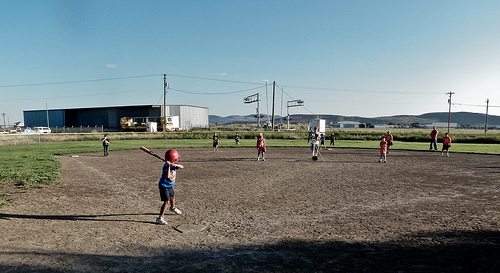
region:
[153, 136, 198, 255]
A kid playing baseball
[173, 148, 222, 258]
A kid playing baseball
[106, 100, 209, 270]
A kid playing baseball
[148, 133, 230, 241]
A kid playing baseball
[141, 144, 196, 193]
A kid playing baseball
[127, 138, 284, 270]
A kid is playing baseball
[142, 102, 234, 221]
A kid is playing baseball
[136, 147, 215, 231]
A kid is playing baseball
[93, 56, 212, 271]
A kid is playing baseball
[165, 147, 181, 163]
Red round baseball helmet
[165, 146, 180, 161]
Baseball helmet is red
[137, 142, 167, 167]
Baseball bat in hand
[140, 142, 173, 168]
Long brown baseball bat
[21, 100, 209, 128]
Long grey rectangular building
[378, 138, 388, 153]
Orange baseball jersey shirt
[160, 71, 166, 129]
Long cylinder powerline pole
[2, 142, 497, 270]
Diamond shaped baseball field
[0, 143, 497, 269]
Dirt covered baseball field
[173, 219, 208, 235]
Pentagon shaped home base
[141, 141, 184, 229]
children playing baseball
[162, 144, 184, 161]
red baseball helmet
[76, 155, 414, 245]
tan dirt baseball field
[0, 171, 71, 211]
patches of green grass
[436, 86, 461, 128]
tall brown telephone pole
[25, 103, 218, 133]
grey warehouse in background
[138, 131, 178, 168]
brown and black baseball bat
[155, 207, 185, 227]
small white tennis shoes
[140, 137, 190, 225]
child holding baseball bat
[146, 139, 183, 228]
child wearing white tennis shoes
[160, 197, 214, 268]
A kid playing baseball